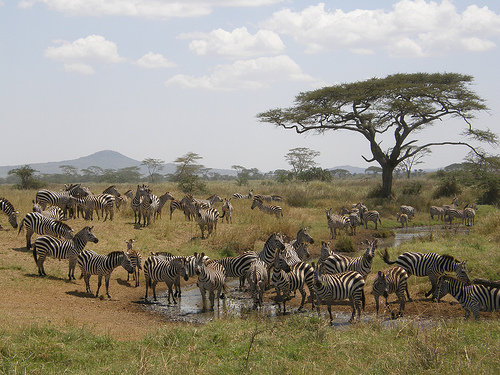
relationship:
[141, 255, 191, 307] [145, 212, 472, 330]
zebra at river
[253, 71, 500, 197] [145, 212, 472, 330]
tree by river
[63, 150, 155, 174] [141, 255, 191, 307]
mountain behind zebra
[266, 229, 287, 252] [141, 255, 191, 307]
head of zebra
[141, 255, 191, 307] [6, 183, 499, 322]
zebra in herd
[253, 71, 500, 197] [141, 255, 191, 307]
tree behind zebra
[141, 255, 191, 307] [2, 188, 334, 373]
zebra on plain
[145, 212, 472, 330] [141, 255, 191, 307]
river by zebra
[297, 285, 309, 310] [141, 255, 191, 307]
leg on zebra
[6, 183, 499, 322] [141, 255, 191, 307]
herd of zebra